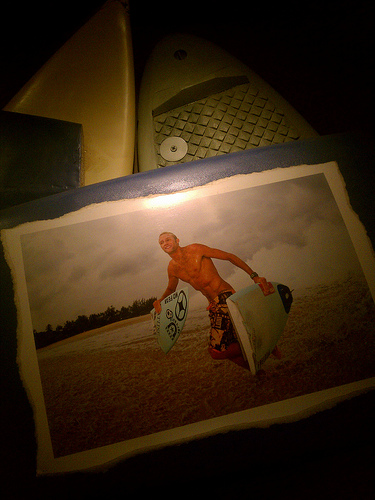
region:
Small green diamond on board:
[153, 113, 165, 124]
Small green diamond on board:
[170, 111, 182, 122]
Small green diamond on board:
[179, 102, 209, 123]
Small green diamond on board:
[202, 92, 232, 113]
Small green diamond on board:
[218, 82, 248, 122]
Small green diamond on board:
[161, 122, 207, 142]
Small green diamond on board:
[202, 127, 234, 149]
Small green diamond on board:
[245, 127, 312, 159]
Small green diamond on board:
[154, 120, 237, 155]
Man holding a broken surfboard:
[128, 209, 318, 422]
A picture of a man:
[130, 197, 318, 400]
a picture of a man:
[135, 199, 305, 404]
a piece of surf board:
[137, 286, 204, 363]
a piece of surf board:
[224, 276, 296, 380]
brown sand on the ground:
[110, 369, 159, 413]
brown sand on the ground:
[81, 343, 139, 391]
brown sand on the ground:
[304, 327, 344, 394]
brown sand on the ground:
[82, 371, 119, 425]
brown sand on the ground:
[313, 290, 351, 333]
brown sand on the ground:
[97, 408, 138, 433]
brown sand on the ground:
[100, 332, 153, 381]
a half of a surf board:
[201, 273, 301, 383]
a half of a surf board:
[143, 285, 206, 355]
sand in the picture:
[107, 365, 145, 420]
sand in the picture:
[164, 373, 219, 420]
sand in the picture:
[68, 359, 118, 410]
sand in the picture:
[301, 328, 338, 389]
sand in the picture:
[91, 349, 159, 406]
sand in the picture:
[162, 398, 211, 424]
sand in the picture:
[95, 390, 124, 422]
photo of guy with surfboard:
[22, 314, 334, 469]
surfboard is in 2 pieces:
[158, 291, 268, 347]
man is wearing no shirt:
[155, 247, 232, 301]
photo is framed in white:
[37, 435, 76, 474]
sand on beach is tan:
[94, 369, 146, 409]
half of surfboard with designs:
[150, 295, 180, 363]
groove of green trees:
[65, 322, 107, 334]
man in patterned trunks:
[203, 298, 230, 346]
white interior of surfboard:
[226, 291, 264, 355]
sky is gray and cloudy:
[250, 218, 307, 272]